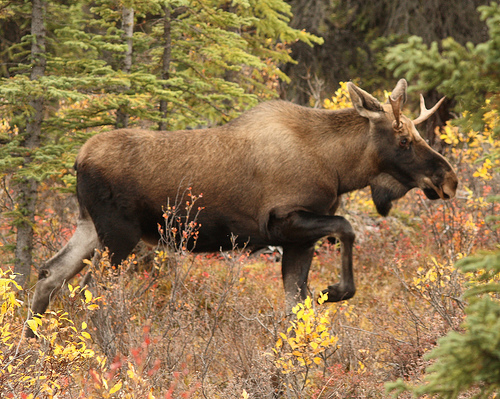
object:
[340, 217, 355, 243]
joints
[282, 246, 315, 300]
leg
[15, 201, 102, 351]
rear leg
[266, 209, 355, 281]
moose's leg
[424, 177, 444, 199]
mouth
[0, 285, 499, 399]
ground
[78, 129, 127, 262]
hindquarters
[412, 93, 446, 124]
antlers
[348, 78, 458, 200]
head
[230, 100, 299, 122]
hump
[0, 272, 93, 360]
grass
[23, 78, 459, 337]
animal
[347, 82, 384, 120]
ears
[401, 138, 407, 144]
eye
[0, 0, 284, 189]
leaves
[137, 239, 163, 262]
bare branches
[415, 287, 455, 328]
bare branches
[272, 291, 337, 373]
grass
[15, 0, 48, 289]
forest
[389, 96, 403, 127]
horns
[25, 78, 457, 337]
elk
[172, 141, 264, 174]
fur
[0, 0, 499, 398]
area